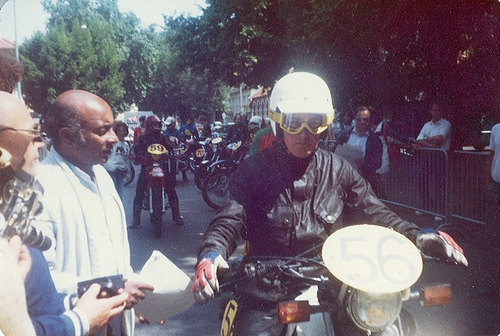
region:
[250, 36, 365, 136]
White helmet on the biker.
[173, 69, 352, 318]
Man on a bicycle.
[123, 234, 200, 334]
Man holding a white paper.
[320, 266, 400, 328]
Light on a bike.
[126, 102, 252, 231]
People on bikes in the background.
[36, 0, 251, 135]
Trees against the sky.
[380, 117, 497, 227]
Fence with people behind.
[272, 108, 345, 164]
Man with goggles on.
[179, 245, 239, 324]
Gloves on a biker.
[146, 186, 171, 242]
Wheel on the motorcycle.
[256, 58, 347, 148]
the helmet is white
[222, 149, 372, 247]
the jacket is black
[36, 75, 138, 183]
the man is bald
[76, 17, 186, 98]
the trees are green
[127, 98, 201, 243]
the man is on a bike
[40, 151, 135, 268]
the shirt is white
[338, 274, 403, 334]
the light is off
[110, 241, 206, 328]
the man is holding paper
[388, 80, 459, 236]
the man is standing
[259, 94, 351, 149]
the glasses are yellow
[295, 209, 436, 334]
bucket on front of handlebars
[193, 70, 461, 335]
cyclist with white helmet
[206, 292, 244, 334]
contestant with a number 5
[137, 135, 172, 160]
entry number 59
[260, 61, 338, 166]
man with yellow googles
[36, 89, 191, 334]
spectator addressing cyclist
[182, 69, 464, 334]
man in a black leather jacket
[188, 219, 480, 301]
man with red, white and blue gloves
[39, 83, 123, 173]
a balding man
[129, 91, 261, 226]
cycles in the shade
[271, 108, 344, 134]
The yellow goggles on the person riding the bike in the front.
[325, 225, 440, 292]
The number in the circle on the front of the motorcycle in the front.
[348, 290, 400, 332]
The headlight on the front of the motorcycle.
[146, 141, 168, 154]
The numbers on the motorcycle in the back.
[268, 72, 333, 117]
The white helmet worn by the rider of the first motorcycle.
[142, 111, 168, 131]
The dark colored helmet worn by the man on the motorcycle in the back.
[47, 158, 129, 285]
The light colored long sleeve jacket the bald man is wearing.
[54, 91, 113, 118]
The bald area on the man's head.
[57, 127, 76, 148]
The bald man's ear.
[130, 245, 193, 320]
The white papers in the bald man's hands.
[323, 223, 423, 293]
white circle on front of motorcycle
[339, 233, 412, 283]
"56" on white circle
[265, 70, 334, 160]
white helmet on head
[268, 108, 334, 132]
yellow goggles on eyes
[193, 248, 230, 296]
glove on right hand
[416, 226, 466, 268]
glove on left hand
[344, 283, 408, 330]
head light on front of motorcycle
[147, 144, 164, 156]
yellow circle on motorcycle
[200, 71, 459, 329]
man riding front motorcycle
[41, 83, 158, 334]
bald man next to motorcycle